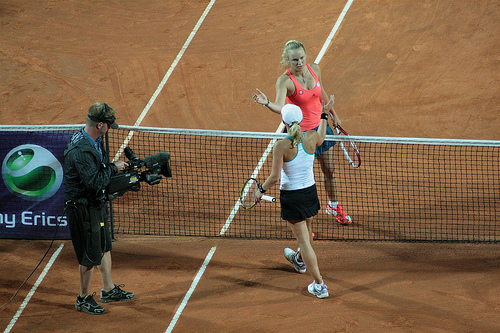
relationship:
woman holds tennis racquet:
[256, 38, 353, 224] [327, 110, 365, 170]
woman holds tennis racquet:
[258, 96, 336, 301] [236, 176, 277, 212]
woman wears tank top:
[256, 38, 353, 224] [283, 62, 323, 128]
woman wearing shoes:
[256, 38, 353, 224] [324, 199, 354, 225]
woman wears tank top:
[258, 96, 336, 301] [273, 130, 317, 189]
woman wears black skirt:
[258, 96, 336, 301] [276, 185, 321, 223]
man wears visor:
[63, 102, 134, 311] [86, 104, 121, 132]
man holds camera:
[63, 102, 134, 311] [90, 148, 174, 198]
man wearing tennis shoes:
[63, 102, 134, 311] [74, 283, 136, 315]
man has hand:
[63, 102, 134, 311] [111, 159, 130, 172]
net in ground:
[1, 123, 499, 244] [2, 1, 500, 332]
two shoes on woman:
[281, 245, 331, 303] [258, 96, 336, 301]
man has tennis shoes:
[63, 102, 134, 311] [281, 245, 331, 303]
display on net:
[1, 130, 99, 239] [1, 123, 499, 244]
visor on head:
[86, 104, 121, 132] [83, 102, 120, 140]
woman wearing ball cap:
[258, 96, 336, 301] [279, 104, 304, 126]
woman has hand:
[256, 38, 353, 224] [252, 86, 269, 109]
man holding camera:
[63, 102, 134, 311] [90, 148, 174, 198]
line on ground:
[106, 0, 229, 127] [2, 1, 500, 332]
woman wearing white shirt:
[258, 96, 336, 301] [273, 130, 317, 189]